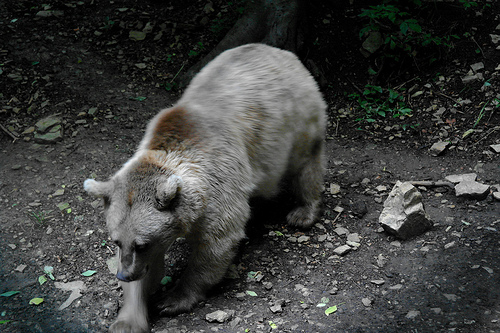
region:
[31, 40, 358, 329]
a bear in a zoo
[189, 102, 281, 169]
the fur of a bear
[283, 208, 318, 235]
the paw of a bear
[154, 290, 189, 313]
the paw of a bear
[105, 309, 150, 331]
the paw of a bear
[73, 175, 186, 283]
the head of a bear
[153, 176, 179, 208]
the ear of a bear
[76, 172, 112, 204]
the ear of a bear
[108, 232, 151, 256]
the eyes of a bear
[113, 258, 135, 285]
the nose of a bear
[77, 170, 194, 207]
two small round ears of bear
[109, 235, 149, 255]
two eyes of bear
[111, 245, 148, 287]
snout of bear is brown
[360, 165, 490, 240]
stones on the ground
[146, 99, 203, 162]
a hump on back the bear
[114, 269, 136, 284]
nose of bear is black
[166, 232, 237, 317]
right leg of bear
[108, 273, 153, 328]
left leg of bear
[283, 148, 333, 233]
back leg of bear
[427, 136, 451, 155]
The rock is gray.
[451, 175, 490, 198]
The rock is gray.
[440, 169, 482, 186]
The rock is gray.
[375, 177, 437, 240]
The rock is gray.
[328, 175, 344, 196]
The rock is gray.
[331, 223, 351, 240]
The rock is gray.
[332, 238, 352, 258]
The rock is gray.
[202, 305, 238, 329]
The rock is gray.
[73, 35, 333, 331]
The bear is gray and brown.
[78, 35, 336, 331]
The bear is furry.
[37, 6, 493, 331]
A bear is walking around slowly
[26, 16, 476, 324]
A bear is looking for food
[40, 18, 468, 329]
The bear is doing some hunting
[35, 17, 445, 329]
The bear is out in the forest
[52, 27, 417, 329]
The animal is a big male bear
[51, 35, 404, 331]
The bear is watching for danger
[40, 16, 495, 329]
The bear is looking for a mate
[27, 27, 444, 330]
The bear has big sharp claws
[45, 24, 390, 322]
The bear is enjoying the day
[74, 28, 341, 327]
bear is color brown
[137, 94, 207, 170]
hump is color dark brown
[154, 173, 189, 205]
right round ear of bear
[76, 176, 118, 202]
right round ear of bear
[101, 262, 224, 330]
front legs of bear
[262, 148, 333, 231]
back legs of bear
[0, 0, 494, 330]
field is covered with stones and pebbles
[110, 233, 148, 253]
eyes of bear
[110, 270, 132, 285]
the nose of bear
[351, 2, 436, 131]
small green plants on the ground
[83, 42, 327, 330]
large grey brown bear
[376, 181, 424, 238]
large jagged grey rock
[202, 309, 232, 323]
small jagged grey rock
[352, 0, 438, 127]
small patch of green plants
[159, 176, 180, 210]
large right bear ear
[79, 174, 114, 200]
large furry bear ear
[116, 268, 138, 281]
large round black bear nose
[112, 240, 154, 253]
round dark bear eyes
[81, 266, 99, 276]
small round green leaf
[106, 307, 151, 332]
large furry brown bear paw